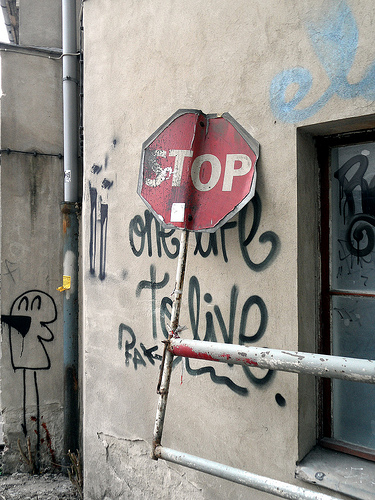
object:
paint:
[170, 345, 258, 369]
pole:
[170, 337, 374, 384]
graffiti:
[90, 163, 285, 405]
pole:
[149, 227, 189, 461]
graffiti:
[1, 288, 58, 451]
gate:
[320, 130, 375, 465]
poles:
[149, 445, 338, 500]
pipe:
[61, 68, 78, 375]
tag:
[56, 275, 71, 293]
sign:
[136, 108, 260, 233]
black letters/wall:
[117, 188, 286, 407]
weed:
[17, 435, 55, 473]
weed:
[68, 450, 81, 473]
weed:
[66, 478, 82, 497]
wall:
[1, 1, 82, 471]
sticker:
[170, 202, 185, 222]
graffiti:
[329, 154, 372, 255]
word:
[126, 203, 188, 263]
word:
[190, 182, 284, 272]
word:
[132, 261, 179, 341]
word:
[181, 271, 287, 396]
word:
[115, 316, 161, 372]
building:
[83, 1, 375, 500]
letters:
[269, 0, 373, 124]